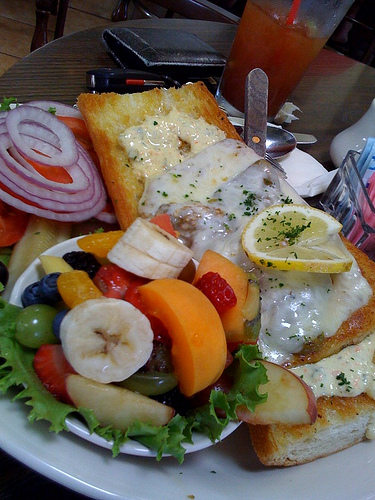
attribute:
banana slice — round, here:
[57, 299, 168, 387]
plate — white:
[5, 92, 374, 494]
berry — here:
[190, 266, 246, 323]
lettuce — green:
[3, 299, 83, 447]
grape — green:
[13, 292, 69, 361]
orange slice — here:
[131, 269, 244, 404]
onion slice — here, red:
[5, 96, 91, 177]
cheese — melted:
[195, 166, 359, 354]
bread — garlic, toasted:
[79, 83, 245, 192]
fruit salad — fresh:
[5, 217, 279, 465]